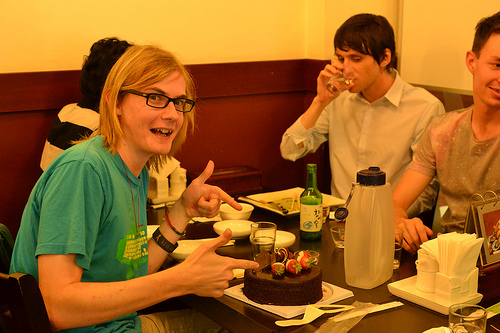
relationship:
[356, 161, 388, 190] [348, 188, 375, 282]
cover on bottle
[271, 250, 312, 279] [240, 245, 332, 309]
strawberries on cake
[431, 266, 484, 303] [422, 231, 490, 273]
holder for napkin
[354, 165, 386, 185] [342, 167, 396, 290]
top on bottle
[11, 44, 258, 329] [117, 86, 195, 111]
man wearing glasses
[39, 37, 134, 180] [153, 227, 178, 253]
person wearing bracelet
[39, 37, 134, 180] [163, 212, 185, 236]
person wearing bracelet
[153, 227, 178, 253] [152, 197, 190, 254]
bracelet on wrist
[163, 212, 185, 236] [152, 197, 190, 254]
bracelet on wrist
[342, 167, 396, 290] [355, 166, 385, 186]
bottle has cover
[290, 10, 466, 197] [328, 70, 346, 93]
person drinking water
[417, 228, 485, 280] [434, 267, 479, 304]
napkins in holder